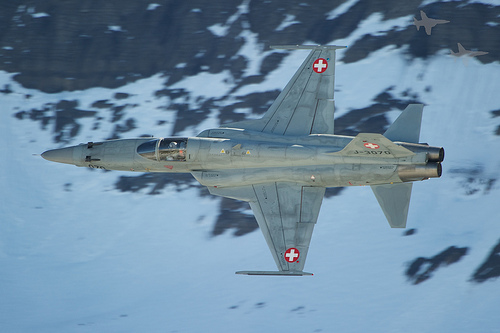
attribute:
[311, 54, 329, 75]
cross — white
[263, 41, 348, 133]
wing — triangular, colorful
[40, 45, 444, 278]
plane — grey, military, flying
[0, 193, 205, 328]
snow — white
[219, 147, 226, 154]
triangle — tiny